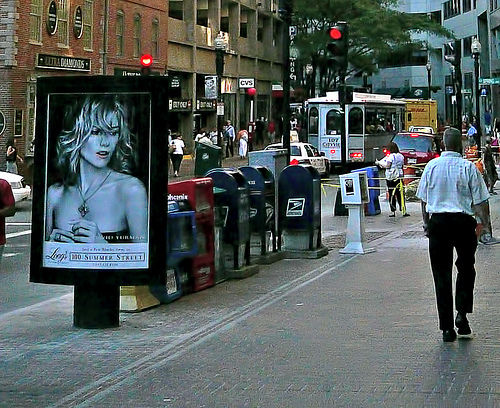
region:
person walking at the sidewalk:
[398, 113, 483, 374]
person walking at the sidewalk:
[172, 127, 194, 190]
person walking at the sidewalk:
[229, 122, 255, 163]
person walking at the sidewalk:
[194, 129, 223, 166]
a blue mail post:
[279, 162, 331, 269]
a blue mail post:
[236, 151, 283, 258]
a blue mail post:
[212, 160, 259, 280]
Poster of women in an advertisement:
[46, 85, 154, 275]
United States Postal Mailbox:
[279, 162, 326, 256]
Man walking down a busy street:
[416, 120, 496, 349]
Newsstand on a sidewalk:
[339, 173, 375, 255]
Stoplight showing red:
[325, 19, 350, 84]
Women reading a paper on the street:
[372, 142, 409, 218]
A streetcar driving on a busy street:
[304, 90, 414, 162]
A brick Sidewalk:
[196, 217, 431, 407]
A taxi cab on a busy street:
[266, 128, 327, 173]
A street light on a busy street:
[470, 38, 487, 176]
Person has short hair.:
[439, 123, 466, 158]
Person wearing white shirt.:
[413, 161, 473, 205]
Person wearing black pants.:
[406, 214, 484, 299]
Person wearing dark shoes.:
[426, 293, 467, 352]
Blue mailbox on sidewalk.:
[280, 168, 335, 253]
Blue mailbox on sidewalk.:
[243, 158, 277, 240]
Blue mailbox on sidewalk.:
[219, 160, 257, 259]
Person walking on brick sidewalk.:
[407, 252, 472, 397]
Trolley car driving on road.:
[310, 79, 385, 156]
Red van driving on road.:
[381, 125, 430, 175]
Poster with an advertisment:
[37, 75, 164, 282]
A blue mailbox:
[272, 158, 322, 260]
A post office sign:
[281, 188, 311, 224]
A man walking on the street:
[417, 121, 490, 352]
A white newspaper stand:
[335, 169, 377, 261]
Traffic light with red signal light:
[322, 13, 349, 78]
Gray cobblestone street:
[246, 319, 366, 400]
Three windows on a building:
[107, 10, 166, 58]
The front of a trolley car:
[305, 94, 377, 164]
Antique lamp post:
[467, 33, 487, 95]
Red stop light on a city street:
[320, 19, 354, 74]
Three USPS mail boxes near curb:
[213, 165, 328, 271]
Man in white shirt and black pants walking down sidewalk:
[417, 124, 484, 328]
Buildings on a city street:
[5, 2, 274, 71]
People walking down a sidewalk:
[174, 112, 303, 148]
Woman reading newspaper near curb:
[372, 141, 410, 220]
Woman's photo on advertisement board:
[22, 64, 168, 305]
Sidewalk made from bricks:
[140, 320, 432, 380]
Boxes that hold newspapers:
[168, 174, 218, 300]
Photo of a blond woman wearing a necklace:
[50, 96, 146, 221]